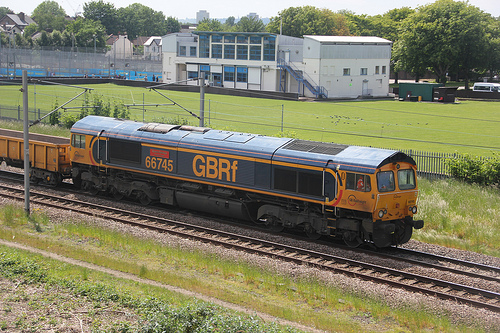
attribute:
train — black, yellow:
[97, 110, 442, 279]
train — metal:
[92, 83, 461, 284]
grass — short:
[90, 266, 204, 331]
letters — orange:
[188, 141, 246, 191]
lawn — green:
[6, 70, 494, 243]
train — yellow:
[0, 106, 420, 250]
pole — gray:
[16, 73, 36, 212]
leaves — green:
[392, 4, 493, 77]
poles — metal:
[12, 72, 215, 221]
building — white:
[158, 23, 403, 105]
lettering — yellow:
[184, 142, 244, 189]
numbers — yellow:
[136, 150, 179, 181]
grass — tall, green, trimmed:
[2, 73, 497, 326]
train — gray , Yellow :
[32, 80, 432, 256]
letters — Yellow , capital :
[165, 114, 255, 203]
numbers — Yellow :
[125, 111, 301, 216]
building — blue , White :
[119, 4, 432, 139]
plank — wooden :
[125, 192, 182, 240]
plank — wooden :
[93, 190, 178, 292]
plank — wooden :
[188, 212, 224, 266]